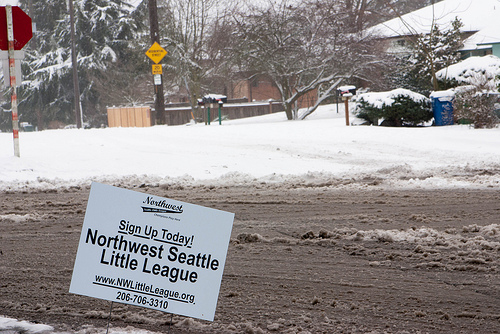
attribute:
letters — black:
[81, 225, 226, 287]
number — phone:
[113, 287, 173, 310]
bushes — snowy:
[354, 84, 436, 128]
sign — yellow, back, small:
[147, 42, 168, 75]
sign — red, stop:
[0, 6, 35, 54]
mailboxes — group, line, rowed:
[198, 90, 230, 126]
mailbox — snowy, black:
[338, 84, 359, 125]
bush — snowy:
[443, 82, 499, 130]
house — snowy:
[347, 1, 499, 54]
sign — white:
[70, 181, 237, 323]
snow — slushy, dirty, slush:
[0, 102, 500, 192]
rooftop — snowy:
[342, 0, 500, 38]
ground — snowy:
[1, 102, 499, 334]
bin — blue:
[432, 95, 455, 126]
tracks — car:
[21, 185, 417, 226]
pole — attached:
[8, 49, 22, 157]